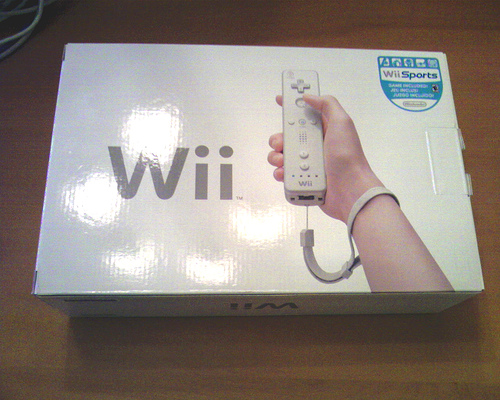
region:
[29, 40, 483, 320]
box of wii game console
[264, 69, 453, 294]
person's hand holding wii game controller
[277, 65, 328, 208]
wii game controller displayed on box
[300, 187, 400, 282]
wrist handle on wii game controller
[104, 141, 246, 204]
wii symbol on box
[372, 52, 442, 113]
wii sports symbol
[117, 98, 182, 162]
glare from light on wii box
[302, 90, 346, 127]
person's thumb on wii box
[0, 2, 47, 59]
cords in upper left corner of picture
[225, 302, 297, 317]
wii symbol on side of box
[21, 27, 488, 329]
the box is white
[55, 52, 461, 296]
the box is shiny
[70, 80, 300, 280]
lights reflecting off the box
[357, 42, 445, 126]
a blue wii label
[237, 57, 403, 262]
the wii remote on the box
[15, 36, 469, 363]
the box is on the table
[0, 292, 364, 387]
the table is tan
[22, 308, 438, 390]
the table is made of wood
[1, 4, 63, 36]
white wires in the top left corner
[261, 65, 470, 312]
the hand is white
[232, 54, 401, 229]
controller in a person's hand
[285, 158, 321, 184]
circle on the remote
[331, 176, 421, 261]
strap around the wrist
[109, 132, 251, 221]
letters on the box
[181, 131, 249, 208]
two of the same letter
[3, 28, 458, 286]
box with a game system inside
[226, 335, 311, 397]
brown table under box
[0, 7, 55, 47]
wire next to the box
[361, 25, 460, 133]
logo on the box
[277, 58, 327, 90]
top part of the controller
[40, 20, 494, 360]
a wii box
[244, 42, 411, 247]
a white wii remote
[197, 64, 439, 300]
a hand holding a white wii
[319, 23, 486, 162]
a wii sports sticker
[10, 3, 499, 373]
a closes wii box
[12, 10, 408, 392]
a box that holds a wii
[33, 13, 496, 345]
a box for a wii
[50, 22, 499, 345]
a box with a wii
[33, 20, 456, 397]
a box with a white wii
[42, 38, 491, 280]
Wii box with assorted graphics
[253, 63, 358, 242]
Wii controller in user's hand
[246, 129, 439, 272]
Wii secured to user's hand image on box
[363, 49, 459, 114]
WiiSports sticker affixed to Wii box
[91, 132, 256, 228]
Wii logo on box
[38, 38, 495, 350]
Wii box resting on wood table or floor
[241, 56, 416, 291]
Wii remote in hand on Wii box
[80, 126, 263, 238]
Wii trademarked logo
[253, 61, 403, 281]
Wii remote image on Wii box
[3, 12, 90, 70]
cables in background